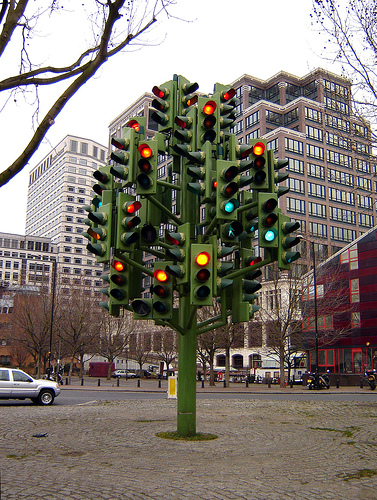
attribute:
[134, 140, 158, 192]
traffic light — red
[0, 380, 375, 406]
road — grey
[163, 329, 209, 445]
pole — green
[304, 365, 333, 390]
motorcycle — parked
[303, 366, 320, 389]
motorcycle — parked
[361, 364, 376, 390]
motorcycle — parked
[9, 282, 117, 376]
tree — bare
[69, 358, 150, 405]
car — red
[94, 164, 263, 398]
pole — green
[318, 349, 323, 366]
window — red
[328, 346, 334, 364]
window — red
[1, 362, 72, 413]
van — silver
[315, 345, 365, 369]
frames — bright